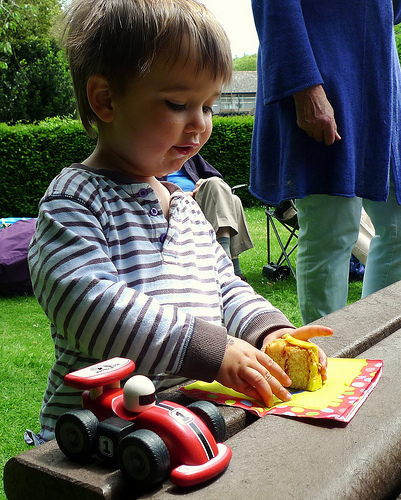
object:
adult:
[249, 0, 400, 328]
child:
[26, 0, 331, 451]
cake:
[263, 332, 325, 391]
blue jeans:
[291, 192, 400, 324]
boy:
[28, 1, 333, 449]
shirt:
[26, 161, 299, 445]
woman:
[246, 0, 401, 328]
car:
[53, 356, 234, 487]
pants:
[293, 191, 401, 326]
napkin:
[177, 354, 384, 426]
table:
[6, 280, 401, 500]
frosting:
[284, 326, 329, 338]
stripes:
[26, 167, 268, 435]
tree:
[0, 0, 78, 120]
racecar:
[54, 355, 234, 488]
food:
[263, 333, 323, 393]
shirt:
[26, 163, 295, 444]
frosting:
[282, 332, 314, 349]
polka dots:
[180, 385, 345, 425]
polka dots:
[321, 352, 386, 425]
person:
[247, 0, 400, 328]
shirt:
[246, 0, 400, 204]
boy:
[21, 0, 335, 445]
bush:
[0, 113, 257, 216]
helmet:
[121, 373, 157, 409]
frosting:
[312, 343, 327, 368]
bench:
[0, 275, 400, 497]